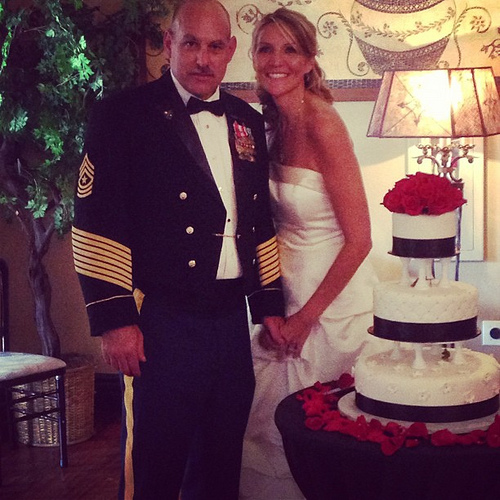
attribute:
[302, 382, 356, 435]
petals — red, rose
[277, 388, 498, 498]
table cloth — black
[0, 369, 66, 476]
legs — black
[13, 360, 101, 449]
basket — wicker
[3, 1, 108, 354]
tree — fake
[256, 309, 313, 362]
hands — holding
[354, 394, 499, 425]
trimming — black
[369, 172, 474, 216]
roses — red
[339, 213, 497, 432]
wedding cake — black, white, tiered, navy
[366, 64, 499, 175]
lamp — lit, decorative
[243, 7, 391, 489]
bride — posing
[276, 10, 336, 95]
hair — blonde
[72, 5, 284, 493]
groom — balding, posing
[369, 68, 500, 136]
lamp shade — light brown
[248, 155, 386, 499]
wedding dress — strapless, white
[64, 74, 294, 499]
uniform — military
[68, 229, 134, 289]
stripes — golden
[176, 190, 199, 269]
buttons — silver, small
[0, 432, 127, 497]
flooring — board, dark, wooden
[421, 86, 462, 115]
light — illuminated